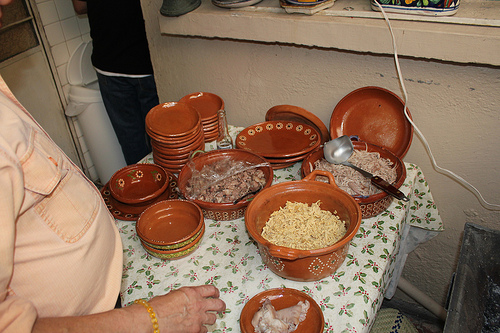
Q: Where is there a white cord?
A: Hanging on wall behind dishes.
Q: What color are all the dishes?
A: Brown.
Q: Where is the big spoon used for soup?
A: On top of food closest to wall.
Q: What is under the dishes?
A: Tablecloth.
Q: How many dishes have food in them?
A: Four.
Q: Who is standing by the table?
A: Person in peach color shirt.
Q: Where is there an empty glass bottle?
A: Table between plates and bowls.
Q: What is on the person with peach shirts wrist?
A: Yellow band.